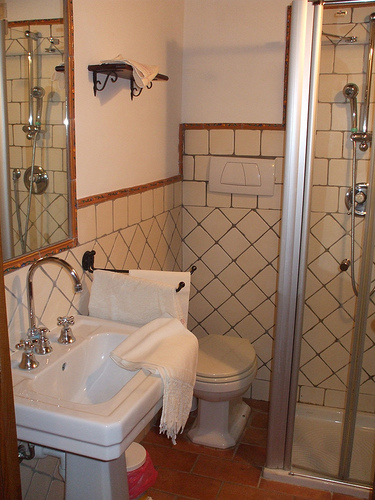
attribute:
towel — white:
[112, 311, 199, 445]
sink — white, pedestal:
[9, 312, 163, 499]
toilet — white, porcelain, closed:
[187, 332, 259, 450]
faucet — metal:
[25, 256, 83, 336]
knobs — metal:
[12, 314, 76, 370]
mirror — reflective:
[0, 0, 70, 263]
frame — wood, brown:
[0, 2, 79, 275]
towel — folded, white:
[101, 53, 159, 90]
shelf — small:
[86, 62, 169, 102]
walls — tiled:
[1, 0, 374, 500]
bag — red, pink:
[127, 452, 158, 499]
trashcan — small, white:
[124, 442, 151, 499]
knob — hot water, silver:
[14, 334, 38, 373]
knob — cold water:
[56, 314, 78, 346]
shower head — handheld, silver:
[341, 83, 362, 142]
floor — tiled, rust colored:
[133, 395, 374, 499]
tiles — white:
[5, 5, 374, 500]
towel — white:
[88, 271, 184, 330]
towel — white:
[130, 267, 191, 332]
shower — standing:
[263, 0, 373, 500]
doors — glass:
[293, 3, 372, 491]